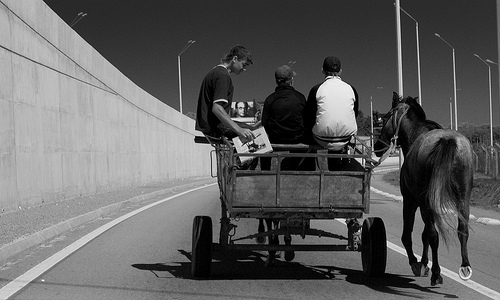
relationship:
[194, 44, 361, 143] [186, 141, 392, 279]
people riding in wagon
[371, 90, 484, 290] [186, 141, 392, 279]
horse next to wagon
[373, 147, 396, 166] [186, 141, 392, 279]
rope attached to wagon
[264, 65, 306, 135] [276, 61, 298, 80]
man wearing cap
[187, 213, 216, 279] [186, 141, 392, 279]
wheel of wagon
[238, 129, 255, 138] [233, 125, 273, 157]
hand holding magazine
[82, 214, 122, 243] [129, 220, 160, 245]
line painted on street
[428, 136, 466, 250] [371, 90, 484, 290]
tail of a horse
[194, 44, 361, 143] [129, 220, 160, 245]
people moving down street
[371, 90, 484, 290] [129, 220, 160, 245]
horse walking down street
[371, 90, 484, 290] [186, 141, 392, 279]
horse walking beside wagon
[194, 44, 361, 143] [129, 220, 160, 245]
people currently on street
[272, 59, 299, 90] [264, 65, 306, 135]
head of a man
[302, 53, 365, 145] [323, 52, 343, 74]
man wearing cap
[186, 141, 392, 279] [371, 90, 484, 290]
wagon and a horse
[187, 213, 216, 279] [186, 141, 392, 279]
wheel of a wagon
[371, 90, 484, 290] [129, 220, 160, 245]
horse walking on street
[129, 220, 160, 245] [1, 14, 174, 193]
street next to wall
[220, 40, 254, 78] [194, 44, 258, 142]
head of a people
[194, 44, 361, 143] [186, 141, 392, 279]
people sitting in wagon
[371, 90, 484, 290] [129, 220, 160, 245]
horse walking on a street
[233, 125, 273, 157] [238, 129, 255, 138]
magazine gripped by hand